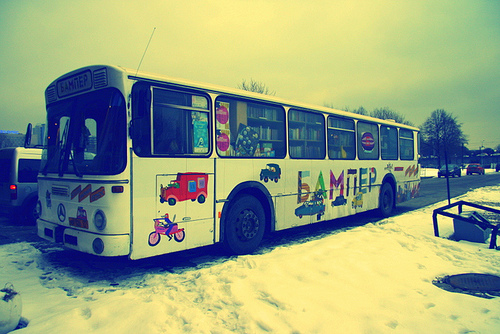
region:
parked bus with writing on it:
[30, 71, 436, 290]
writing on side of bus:
[284, 155, 390, 219]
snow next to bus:
[298, 248, 353, 283]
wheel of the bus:
[217, 186, 283, 253]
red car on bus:
[153, 161, 216, 211]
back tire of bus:
[369, 166, 411, 216]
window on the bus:
[281, 106, 336, 167]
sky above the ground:
[331, 6, 396, 45]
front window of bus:
[36, 83, 123, 168]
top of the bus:
[43, 70, 97, 101]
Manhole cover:
[425, 255, 499, 305]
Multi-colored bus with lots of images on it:
[35, 56, 439, 231]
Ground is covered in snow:
[164, 266, 421, 323]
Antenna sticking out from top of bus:
[114, 4, 179, 71]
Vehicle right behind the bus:
[3, 138, 44, 235]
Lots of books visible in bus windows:
[226, 92, 413, 162]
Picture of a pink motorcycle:
[134, 210, 204, 252]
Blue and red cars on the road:
[427, 150, 497, 182]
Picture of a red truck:
[150, 162, 227, 213]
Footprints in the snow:
[170, 268, 263, 332]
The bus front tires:
[234, 197, 268, 253]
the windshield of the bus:
[49, 120, 127, 163]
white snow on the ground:
[278, 261, 378, 321]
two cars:
[438, 161, 483, 175]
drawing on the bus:
[141, 211, 194, 244]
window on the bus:
[289, 115, 323, 157]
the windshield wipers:
[59, 138, 84, 170]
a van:
[8, 148, 30, 205]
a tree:
[428, 112, 454, 139]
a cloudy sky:
[259, 25, 397, 88]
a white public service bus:
[35, 64, 420, 276]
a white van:
[5, 139, 43, 221]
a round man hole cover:
[435, 267, 497, 297]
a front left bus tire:
[215, 189, 272, 254]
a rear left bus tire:
[378, 178, 397, 218]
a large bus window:
[131, 84, 211, 159]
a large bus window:
[211, 93, 286, 159]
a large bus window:
[287, 107, 327, 162]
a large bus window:
[326, 112, 356, 163]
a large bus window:
[352, 116, 380, 163]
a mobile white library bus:
[37, 63, 422, 260]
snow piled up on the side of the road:
[179, 235, 449, 332]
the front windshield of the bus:
[46, 87, 124, 178]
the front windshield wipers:
[42, 116, 67, 173]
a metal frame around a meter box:
[431, 199, 498, 249]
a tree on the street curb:
[422, 107, 467, 201]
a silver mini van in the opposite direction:
[1, 147, 34, 223]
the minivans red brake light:
[8, 183, 16, 198]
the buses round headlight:
[92, 209, 105, 229]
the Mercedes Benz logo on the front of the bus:
[55, 201, 67, 221]